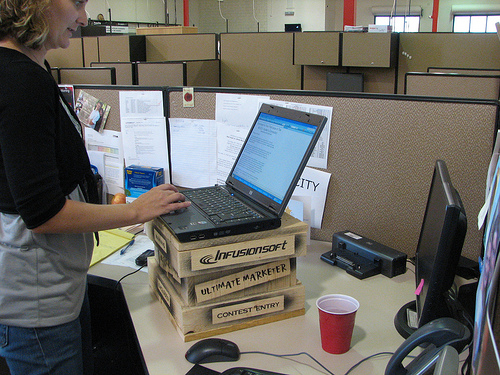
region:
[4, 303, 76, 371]
Leg of a person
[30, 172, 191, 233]
Hand of a person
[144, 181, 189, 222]
Fingers of a person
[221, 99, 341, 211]
Screen of a laptop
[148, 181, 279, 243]
Keyboard of a laptop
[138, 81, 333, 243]
This is a laptop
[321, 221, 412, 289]
This is a printer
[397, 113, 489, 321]
This is a monitor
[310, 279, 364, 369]
This is a cup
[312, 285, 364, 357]
This is a disposable cup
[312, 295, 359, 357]
A red plastic cup.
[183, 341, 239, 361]
A black computer mouse.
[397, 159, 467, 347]
A black flatscreen computer monitor.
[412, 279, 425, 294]
A bright pink stick it note.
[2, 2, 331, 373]
A woman typing on a laptop.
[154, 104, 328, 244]
A black laptop.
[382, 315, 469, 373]
A grey telephone.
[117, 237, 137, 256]
A blue pen.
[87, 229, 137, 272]
A yellow notepad.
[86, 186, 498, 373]
An office desk.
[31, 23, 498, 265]
Several cubicles with dark trim.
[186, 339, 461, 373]
Black computer mouse with cord.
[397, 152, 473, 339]
Black flat screen monitor.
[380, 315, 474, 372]
Black phone for communication.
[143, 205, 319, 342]
Brown wooden box to raise up laptop.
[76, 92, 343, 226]
Several sheets of paper for reminders.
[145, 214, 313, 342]
Writing on side of box.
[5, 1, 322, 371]
Lady working on lap top.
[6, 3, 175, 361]
Lady with black tied sweater.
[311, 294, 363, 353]
Red and white plastic disposable cup.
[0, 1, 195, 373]
woman in jeans using laptop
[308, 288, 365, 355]
red plastic drinking cup on office desk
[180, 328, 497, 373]
black mouse with wire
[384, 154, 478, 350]
black flat screen computer screen that is now turned off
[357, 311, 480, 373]
dark gray office telephone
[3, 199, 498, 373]
hard white office desk surface within cubicle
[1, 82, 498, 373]
light gray cubicle wall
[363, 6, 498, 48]
clear glass windows letting in bright light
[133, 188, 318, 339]
square white and black boxes supporting laptop computer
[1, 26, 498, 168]
large section of light brown and gray cubicle walls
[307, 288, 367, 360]
A red cup on a desk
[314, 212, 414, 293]
A laptop docking station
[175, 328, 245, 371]
A computer mouse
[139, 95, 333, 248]
A black laptop computer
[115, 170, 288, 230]
Someone using a keyboard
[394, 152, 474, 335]
A computer monitor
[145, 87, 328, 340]
A laptop on boxes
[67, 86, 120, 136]
A picture hung on a wall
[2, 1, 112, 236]
A woman in a black sweater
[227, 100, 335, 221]
A laptop screen